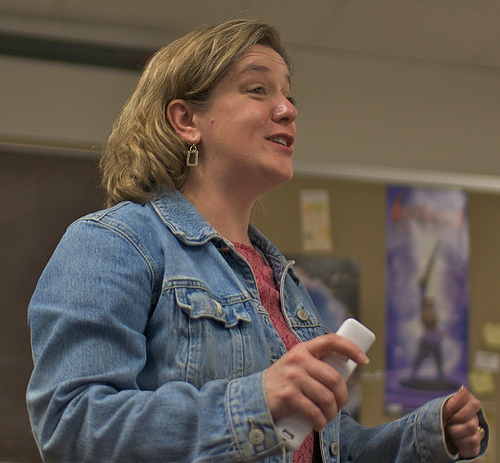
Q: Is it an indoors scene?
A: Yes, it is indoors.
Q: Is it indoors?
A: Yes, it is indoors.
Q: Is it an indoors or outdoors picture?
A: It is indoors.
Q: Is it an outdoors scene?
A: No, it is indoors.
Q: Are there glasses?
A: No, there are no glasses.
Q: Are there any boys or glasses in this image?
A: No, there are no glasses or boys.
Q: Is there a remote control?
A: Yes, there is a remote control.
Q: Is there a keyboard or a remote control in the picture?
A: Yes, there is a remote control.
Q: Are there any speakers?
A: No, there are no speakers.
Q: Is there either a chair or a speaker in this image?
A: No, there are no speakers or chairs.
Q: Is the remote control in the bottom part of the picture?
A: Yes, the remote control is in the bottom of the image.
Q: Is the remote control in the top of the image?
A: No, the remote control is in the bottom of the image.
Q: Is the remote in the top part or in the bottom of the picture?
A: The remote is in the bottom of the image.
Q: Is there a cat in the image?
A: No, there are no cats.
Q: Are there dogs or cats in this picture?
A: No, there are no cats or dogs.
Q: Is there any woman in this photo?
A: Yes, there is a woman.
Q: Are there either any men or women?
A: Yes, there is a woman.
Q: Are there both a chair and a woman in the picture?
A: No, there is a woman but no chairs.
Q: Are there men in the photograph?
A: No, there are no men.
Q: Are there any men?
A: No, there are no men.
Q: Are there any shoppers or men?
A: No, there are no men or shoppers.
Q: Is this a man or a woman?
A: This is a woman.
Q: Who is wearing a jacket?
A: The woman is wearing a jacket.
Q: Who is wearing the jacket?
A: The woman is wearing a jacket.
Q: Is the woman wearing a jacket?
A: Yes, the woman is wearing a jacket.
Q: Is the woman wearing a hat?
A: No, the woman is wearing a jacket.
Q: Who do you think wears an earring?
A: The woman wears an earring.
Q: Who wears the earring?
A: The woman wears an earring.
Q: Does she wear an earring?
A: Yes, the woman wears an earring.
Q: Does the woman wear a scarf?
A: No, the woman wears an earring.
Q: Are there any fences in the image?
A: No, there are no fences.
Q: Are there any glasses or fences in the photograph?
A: No, there are no fences or glasses.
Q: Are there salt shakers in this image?
A: No, there are no salt shakers.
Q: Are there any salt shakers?
A: No, there are no salt shakers.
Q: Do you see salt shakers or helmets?
A: No, there are no salt shakers or helmets.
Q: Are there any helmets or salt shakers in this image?
A: No, there are no salt shakers or helmets.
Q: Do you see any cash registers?
A: No, there are no cash registers.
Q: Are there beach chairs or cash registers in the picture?
A: No, there are no cash registers or beach chairs.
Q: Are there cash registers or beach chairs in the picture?
A: No, there are no cash registers or beach chairs.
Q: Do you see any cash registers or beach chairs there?
A: No, there are no cash registers or beach chairs.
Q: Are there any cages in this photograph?
A: No, there are no cages.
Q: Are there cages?
A: No, there are no cages.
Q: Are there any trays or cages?
A: No, there are no cages or trays.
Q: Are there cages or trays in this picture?
A: No, there are no cages or trays.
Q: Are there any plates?
A: No, there are no plates.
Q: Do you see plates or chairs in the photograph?
A: No, there are no plates or chairs.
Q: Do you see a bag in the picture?
A: No, there are no bags.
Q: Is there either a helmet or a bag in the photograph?
A: No, there are no bags or helmets.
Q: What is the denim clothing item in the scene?
A: The clothing item is a jacket.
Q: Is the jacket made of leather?
A: No, the jacket is made of denim.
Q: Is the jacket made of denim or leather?
A: The jacket is made of denim.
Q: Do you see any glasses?
A: No, there are no glasses.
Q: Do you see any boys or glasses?
A: No, there are no glasses or boys.